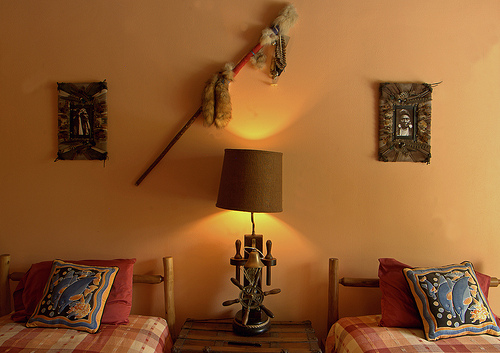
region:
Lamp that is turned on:
[216, 148, 284, 331]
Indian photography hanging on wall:
[375, 67, 441, 187]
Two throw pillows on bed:
[360, 242, 498, 344]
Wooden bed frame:
[2, 253, 187, 330]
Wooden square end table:
[182, 312, 316, 351]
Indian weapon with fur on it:
[127, 0, 311, 193]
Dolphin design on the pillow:
[407, 264, 494, 340]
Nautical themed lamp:
[225, 237, 284, 332]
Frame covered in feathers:
[376, 79, 434, 161]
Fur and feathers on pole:
[251, 5, 306, 87]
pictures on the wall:
[30, 52, 484, 235]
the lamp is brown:
[193, 109, 295, 245]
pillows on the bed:
[36, 242, 498, 334]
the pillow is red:
[25, 260, 142, 330]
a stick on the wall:
[139, 5, 332, 219]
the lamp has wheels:
[216, 260, 292, 341]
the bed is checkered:
[45, 305, 123, 350]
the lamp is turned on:
[215, 140, 301, 234]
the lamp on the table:
[180, 124, 363, 350]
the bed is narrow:
[334, 279, 499, 351]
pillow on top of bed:
[22, 252, 117, 351]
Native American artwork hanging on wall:
[374, 80, 434, 165]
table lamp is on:
[210, 137, 290, 334]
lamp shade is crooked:
[213, 140, 290, 222]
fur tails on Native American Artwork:
[192, 68, 240, 129]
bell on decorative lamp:
[243, 240, 268, 275]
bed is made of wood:
[326, 256, 497, 321]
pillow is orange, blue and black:
[401, 267, 499, 346]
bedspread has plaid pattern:
[0, 313, 166, 350]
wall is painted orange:
[356, 166, 492, 243]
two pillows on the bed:
[18, 255, 171, 347]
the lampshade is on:
[191, 129, 343, 339]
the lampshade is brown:
[175, 133, 293, 328]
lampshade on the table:
[35, 129, 455, 351]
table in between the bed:
[182, 317, 351, 350]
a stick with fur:
[138, 15, 365, 247]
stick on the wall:
[120, 20, 380, 262]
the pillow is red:
[105, 253, 147, 330]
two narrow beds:
[6, 227, 483, 351]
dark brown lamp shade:
[215, 131, 292, 229]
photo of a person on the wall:
[372, 77, 442, 164]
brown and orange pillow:
[25, 254, 120, 336]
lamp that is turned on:
[222, 228, 284, 335]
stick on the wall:
[127, 2, 309, 191]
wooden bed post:
[318, 255, 346, 330]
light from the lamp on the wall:
[212, 72, 297, 142]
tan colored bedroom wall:
[338, 24, 457, 61]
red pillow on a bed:
[18, 255, 134, 327]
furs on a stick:
[200, 62, 235, 133]